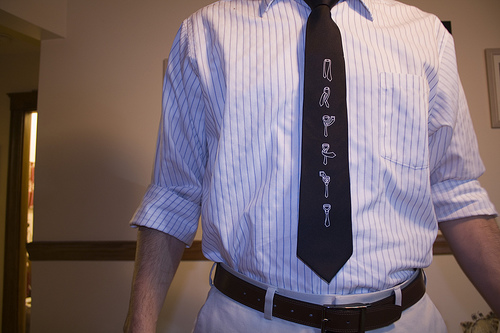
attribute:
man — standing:
[202, 29, 462, 304]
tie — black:
[306, 29, 353, 228]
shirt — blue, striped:
[229, 49, 299, 251]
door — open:
[12, 92, 38, 191]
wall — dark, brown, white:
[65, 40, 142, 143]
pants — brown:
[215, 302, 272, 330]